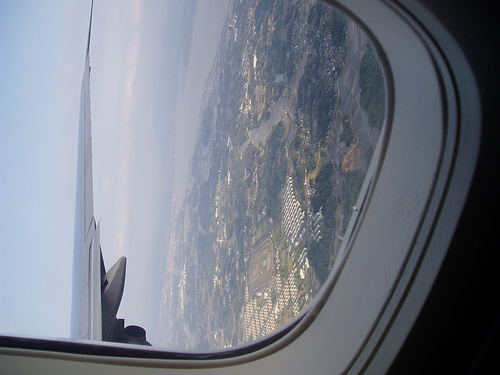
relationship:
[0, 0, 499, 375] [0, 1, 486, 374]
airplane has window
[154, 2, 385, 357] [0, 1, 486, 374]
land outside window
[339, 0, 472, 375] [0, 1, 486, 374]
lines on window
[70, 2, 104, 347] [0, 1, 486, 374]
wing outside window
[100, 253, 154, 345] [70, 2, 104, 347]
engine underneath wing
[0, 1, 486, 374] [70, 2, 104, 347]
window on back of wing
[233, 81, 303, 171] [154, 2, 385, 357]
water curving through land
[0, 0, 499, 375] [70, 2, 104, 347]
airplane has wing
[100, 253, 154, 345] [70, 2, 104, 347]
engine under wing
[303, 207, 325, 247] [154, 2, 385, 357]
houses on ground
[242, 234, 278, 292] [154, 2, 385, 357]
farm on ground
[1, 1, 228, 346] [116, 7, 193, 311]
sky has clouds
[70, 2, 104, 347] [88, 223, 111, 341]
wing has flap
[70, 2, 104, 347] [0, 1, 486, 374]
wing outside of window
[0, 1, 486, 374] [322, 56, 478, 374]
window has edge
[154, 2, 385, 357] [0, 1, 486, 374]
city outside window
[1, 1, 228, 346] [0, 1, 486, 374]
sky outside window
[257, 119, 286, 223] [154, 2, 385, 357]
trees are on ground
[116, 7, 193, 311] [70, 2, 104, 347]
clouds are behind wing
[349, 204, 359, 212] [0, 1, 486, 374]
rivet outside of window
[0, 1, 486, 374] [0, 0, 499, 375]
window in airplane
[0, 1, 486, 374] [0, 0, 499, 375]
window on airplane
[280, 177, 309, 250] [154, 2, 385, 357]
buildings are on ground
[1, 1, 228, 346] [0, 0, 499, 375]
sky above airplane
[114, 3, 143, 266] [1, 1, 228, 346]
cloud in sky